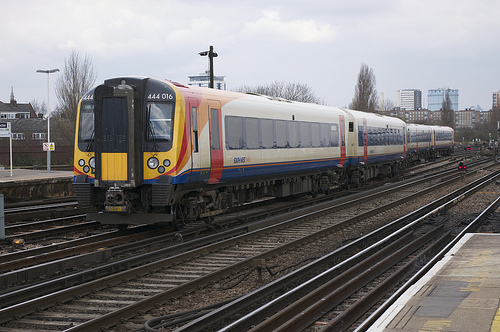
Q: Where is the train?
A: On the tracks.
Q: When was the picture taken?
A: Daytime.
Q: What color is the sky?
A: Blue.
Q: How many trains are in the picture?
A: One.